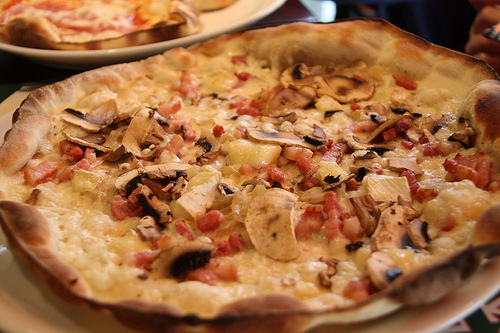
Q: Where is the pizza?
A: On a plate.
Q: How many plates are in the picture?
A: 2.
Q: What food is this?
A: Pizza.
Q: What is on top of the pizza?
A: Spices.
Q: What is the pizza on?
A: A plate.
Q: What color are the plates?
A: White.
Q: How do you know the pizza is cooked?
A: The crust is browned.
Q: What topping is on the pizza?
A: Mushrooms.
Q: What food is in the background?
A: Pizza.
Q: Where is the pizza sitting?
A: On plates.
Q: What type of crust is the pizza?
A: Thin crust.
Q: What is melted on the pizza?
A: Cheese.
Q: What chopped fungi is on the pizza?
A: Mushrooms.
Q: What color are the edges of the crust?
A: Brown.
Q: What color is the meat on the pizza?
A: Red.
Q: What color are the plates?
A: White.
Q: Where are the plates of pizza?
A: At a table.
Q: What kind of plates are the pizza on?
A: Glass.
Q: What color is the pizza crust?
A: Brown.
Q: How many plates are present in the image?
A: 2.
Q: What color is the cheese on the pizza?
A: White.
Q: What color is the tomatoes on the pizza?
A: Red.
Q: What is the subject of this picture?
A: Gourmet pizza.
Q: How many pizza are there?
A: 2.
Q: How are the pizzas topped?
A: Tomato, Chicken, Truffles and mushrooms.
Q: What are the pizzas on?
A: Silver pizza pans.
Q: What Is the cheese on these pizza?
A: Provolone.